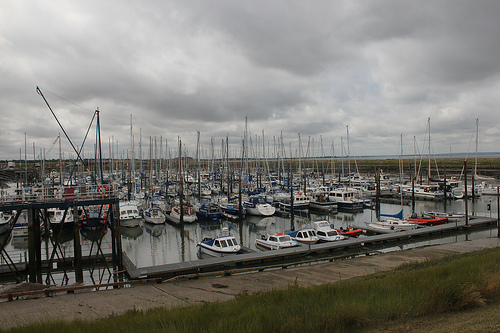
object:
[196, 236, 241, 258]
boat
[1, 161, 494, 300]
harbor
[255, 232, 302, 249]
boat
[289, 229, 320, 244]
boat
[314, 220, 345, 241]
boat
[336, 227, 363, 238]
boat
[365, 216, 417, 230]
boat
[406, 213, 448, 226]
boat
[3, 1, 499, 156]
clouds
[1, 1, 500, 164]
sky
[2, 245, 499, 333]
grass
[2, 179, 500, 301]
water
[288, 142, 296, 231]
pole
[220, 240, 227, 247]
windows